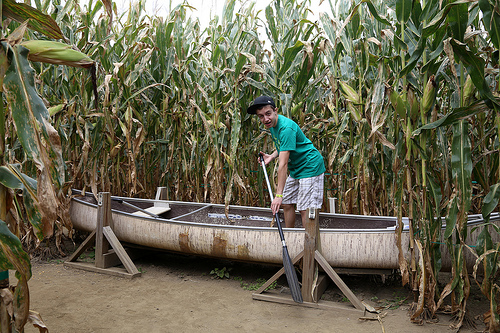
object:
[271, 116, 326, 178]
shirt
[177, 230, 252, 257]
stains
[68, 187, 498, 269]
boat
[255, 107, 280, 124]
face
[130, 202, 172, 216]
bench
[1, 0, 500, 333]
corn field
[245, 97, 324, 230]
boy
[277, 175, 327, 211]
shorts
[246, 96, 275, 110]
cap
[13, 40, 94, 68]
corn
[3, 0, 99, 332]
corn stalk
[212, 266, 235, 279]
green plant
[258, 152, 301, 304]
oar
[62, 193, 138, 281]
stands